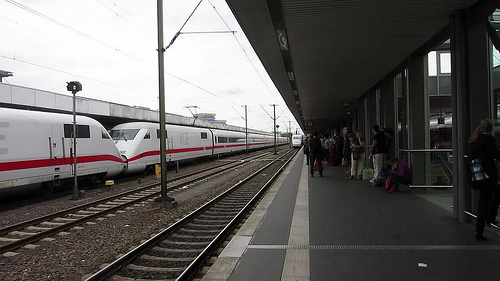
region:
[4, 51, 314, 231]
a train on tracks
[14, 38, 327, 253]
a train at a train station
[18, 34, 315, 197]
a train stop on tracks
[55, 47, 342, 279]
a white train on tracks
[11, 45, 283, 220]
a white train stop on tracks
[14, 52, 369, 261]
a white train stopped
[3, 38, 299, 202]
a white train that is on the tracks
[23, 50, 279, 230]
tracks with a white train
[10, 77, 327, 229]
a white train with a stripe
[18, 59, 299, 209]
a white train with red stripe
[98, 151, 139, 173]
two noses of train touching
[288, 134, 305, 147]
train coming down track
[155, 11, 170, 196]
metal pole by tracks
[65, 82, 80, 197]
metal pole by tracks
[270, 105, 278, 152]
metal pole by tracks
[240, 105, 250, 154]
metal pole by tracks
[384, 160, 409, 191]
person sitting on bench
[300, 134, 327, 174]
person carrying a bag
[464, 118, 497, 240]
person standing on platform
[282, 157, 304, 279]
white stripe on platform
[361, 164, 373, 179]
A small green travel bag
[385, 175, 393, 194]
A small red travel bag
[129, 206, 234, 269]
A black oiled railway line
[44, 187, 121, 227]
A blad oiled railway line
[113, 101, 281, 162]
A white electric passanger train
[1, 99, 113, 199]
A white electric passanger train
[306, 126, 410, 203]
A railway sattion waiting bay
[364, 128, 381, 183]
A man passanger waiting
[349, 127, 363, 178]
A man passanger waiting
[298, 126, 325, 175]
A man passanger waiting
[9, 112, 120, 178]
gray and red passenger train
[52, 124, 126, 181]
gray and red passenger train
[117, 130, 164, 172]
gray and red passenger train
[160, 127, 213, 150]
gray and red passenger train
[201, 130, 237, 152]
gray and red passenger train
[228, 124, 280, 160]
gray and red passenger train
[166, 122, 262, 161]
gray and red passenger train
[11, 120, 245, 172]
gray and red passenger train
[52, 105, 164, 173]
gray and red passenger train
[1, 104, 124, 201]
white and red train car engine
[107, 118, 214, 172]
sleek, white and red train engine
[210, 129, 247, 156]
white and red train car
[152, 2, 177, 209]
grey pole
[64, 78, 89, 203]
train signal on grey pole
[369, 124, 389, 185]
standing man with white pants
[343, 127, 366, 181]
standing woman wearing white pants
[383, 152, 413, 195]
seated woman in pink shirt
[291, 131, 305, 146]
front end of train engine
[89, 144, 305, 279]
train tracks